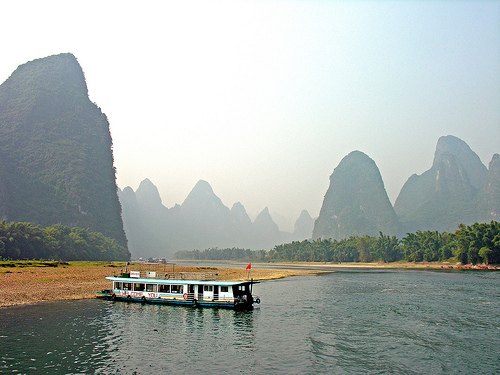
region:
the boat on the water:
[86, 257, 270, 316]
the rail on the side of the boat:
[184, 290, 219, 303]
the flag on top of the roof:
[243, 258, 253, 285]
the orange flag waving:
[244, 258, 254, 270]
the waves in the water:
[269, 311, 451, 373]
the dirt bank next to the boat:
[4, 271, 88, 307]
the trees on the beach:
[1, 218, 131, 263]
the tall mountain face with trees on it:
[0, 50, 133, 244]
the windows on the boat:
[112, 281, 186, 292]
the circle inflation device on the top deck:
[161, 270, 175, 278]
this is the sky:
[432, 28, 484, 85]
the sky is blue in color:
[420, 39, 464, 104]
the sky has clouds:
[206, 35, 325, 116]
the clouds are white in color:
[281, 41, 327, 107]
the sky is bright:
[146, 35, 227, 95]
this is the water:
[310, 295, 407, 368]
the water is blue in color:
[298, 298, 353, 358]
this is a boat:
[87, 251, 256, 321]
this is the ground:
[29, 270, 62, 289]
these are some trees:
[382, 231, 451, 269]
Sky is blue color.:
[296, 37, 488, 129]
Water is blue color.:
[291, 283, 464, 372]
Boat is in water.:
[94, 270, 259, 319]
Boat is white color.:
[101, 270, 246, 315]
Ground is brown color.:
[8, 271, 118, 297]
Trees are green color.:
[198, 238, 499, 266]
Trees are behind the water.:
[171, 230, 499, 283]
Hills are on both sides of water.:
[18, 65, 499, 239]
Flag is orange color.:
[239, 256, 258, 279]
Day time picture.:
[26, 35, 489, 357]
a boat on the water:
[84, 256, 275, 318]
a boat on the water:
[61, 225, 285, 331]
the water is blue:
[265, 320, 342, 371]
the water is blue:
[284, 307, 383, 371]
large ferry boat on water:
[97, 252, 269, 320]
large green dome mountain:
[311, 148, 405, 253]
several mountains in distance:
[134, 178, 299, 233]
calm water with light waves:
[293, 292, 342, 319]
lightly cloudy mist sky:
[199, 59, 271, 106]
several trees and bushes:
[6, 216, 93, 263]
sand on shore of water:
[21, 274, 55, 301]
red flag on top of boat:
[239, 259, 258, 276]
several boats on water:
[137, 250, 171, 267]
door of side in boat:
[190, 283, 228, 303]